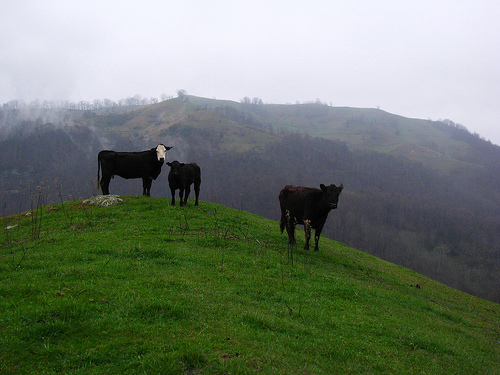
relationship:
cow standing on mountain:
[93, 142, 174, 198] [4, 195, 499, 372]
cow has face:
[93, 142, 174, 198] [152, 141, 173, 164]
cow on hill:
[93, 142, 174, 198] [4, 195, 499, 372]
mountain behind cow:
[4, 94, 496, 307] [93, 142, 174, 198]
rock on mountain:
[82, 190, 126, 207] [4, 195, 499, 372]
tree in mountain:
[232, 91, 272, 118] [4, 94, 496, 307]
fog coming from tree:
[20, 76, 85, 124] [30, 110, 46, 136]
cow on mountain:
[164, 156, 211, 204] [4, 195, 499, 372]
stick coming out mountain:
[214, 224, 236, 272] [4, 195, 499, 372]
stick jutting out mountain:
[214, 224, 236, 272] [4, 195, 499, 372]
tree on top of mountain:
[232, 91, 272, 118] [4, 94, 496, 307]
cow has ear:
[93, 142, 174, 198] [162, 140, 175, 152]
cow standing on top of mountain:
[164, 156, 211, 204] [4, 195, 499, 372]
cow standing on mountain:
[269, 174, 345, 250] [4, 195, 499, 372]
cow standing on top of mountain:
[93, 142, 174, 198] [4, 195, 499, 372]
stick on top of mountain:
[214, 224, 236, 272] [4, 195, 499, 372]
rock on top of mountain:
[82, 190, 126, 207] [4, 195, 499, 372]